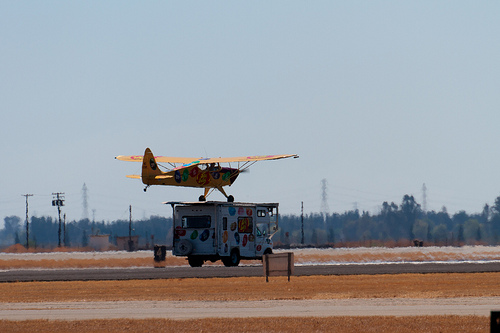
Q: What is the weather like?
A: It is clear.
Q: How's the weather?
A: It is clear.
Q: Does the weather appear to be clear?
A: Yes, it is clear.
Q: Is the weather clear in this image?
A: Yes, it is clear.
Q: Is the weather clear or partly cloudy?
A: It is clear.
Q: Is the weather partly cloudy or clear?
A: It is clear.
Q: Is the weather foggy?
A: No, it is clear.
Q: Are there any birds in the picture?
A: No, there are no birds.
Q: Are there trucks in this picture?
A: Yes, there is a truck.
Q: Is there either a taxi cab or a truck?
A: Yes, there is a truck.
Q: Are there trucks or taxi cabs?
A: Yes, there is a truck.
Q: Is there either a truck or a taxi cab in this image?
A: Yes, there is a truck.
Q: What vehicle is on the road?
A: The vehicle is a truck.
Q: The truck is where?
A: The truck is on the road.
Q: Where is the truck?
A: The truck is on the road.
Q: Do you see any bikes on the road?
A: No, there is a truck on the road.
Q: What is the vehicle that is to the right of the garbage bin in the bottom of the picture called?
A: The vehicle is a truck.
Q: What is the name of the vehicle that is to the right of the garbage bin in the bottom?
A: The vehicle is a truck.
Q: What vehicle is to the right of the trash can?
A: The vehicle is a truck.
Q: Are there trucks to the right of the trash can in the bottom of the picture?
A: Yes, there is a truck to the right of the trashcan.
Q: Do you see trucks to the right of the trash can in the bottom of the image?
A: Yes, there is a truck to the right of the trashcan.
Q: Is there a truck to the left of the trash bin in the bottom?
A: No, the truck is to the right of the garbage can.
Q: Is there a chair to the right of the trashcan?
A: No, there is a truck to the right of the trashcan.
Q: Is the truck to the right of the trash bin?
A: Yes, the truck is to the right of the trash bin.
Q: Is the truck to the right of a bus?
A: No, the truck is to the right of the trash bin.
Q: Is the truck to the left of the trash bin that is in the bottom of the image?
A: No, the truck is to the right of the trash bin.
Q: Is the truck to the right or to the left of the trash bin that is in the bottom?
A: The truck is to the right of the garbage can.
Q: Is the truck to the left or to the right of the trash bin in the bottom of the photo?
A: The truck is to the right of the garbage can.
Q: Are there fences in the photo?
A: No, there are no fences.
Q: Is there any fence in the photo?
A: No, there are no fences.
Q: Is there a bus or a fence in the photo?
A: No, there are no fences or buses.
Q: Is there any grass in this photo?
A: Yes, there is grass.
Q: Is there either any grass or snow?
A: Yes, there is grass.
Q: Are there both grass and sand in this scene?
A: No, there is grass but no sand.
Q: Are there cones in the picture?
A: No, there are no cones.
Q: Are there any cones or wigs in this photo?
A: No, there are no cones or wigs.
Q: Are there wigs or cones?
A: No, there are no cones or wigs.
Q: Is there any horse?
A: No, there are no horses.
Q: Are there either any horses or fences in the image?
A: No, there are no horses or fences.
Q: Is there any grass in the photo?
A: Yes, there is grass.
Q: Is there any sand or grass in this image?
A: Yes, there is grass.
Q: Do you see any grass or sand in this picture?
A: Yes, there is grass.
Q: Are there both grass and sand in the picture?
A: No, there is grass but no sand.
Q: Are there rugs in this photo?
A: No, there are no rugs.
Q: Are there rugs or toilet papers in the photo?
A: No, there are no rugs or toilet papers.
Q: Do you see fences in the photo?
A: No, there are no fences.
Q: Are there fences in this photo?
A: No, there are no fences.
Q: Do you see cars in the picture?
A: No, there are no cars.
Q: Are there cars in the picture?
A: No, there are no cars.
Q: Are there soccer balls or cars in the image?
A: No, there are no cars or soccer balls.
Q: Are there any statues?
A: No, there are no statues.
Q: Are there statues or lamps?
A: No, there are no statues or lamps.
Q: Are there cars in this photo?
A: No, there are no cars.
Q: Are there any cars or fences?
A: No, there are no cars or fences.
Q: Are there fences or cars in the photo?
A: No, there are no cars or fences.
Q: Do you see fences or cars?
A: No, there are no cars or fences.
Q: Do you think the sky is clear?
A: Yes, the sky is clear.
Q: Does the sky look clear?
A: Yes, the sky is clear.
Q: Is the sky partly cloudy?
A: No, the sky is clear.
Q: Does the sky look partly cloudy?
A: No, the sky is clear.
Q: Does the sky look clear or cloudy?
A: The sky is clear.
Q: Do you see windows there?
A: Yes, there is a window.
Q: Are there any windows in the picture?
A: Yes, there is a window.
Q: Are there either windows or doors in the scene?
A: Yes, there is a window.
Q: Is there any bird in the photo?
A: No, there are no birds.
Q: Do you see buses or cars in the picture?
A: No, there are no cars or buses.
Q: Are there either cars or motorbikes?
A: No, there are no cars or motorbikes.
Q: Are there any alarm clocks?
A: No, there are no alarm clocks.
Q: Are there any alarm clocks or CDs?
A: No, there are no alarm clocks or cds.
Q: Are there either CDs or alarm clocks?
A: No, there are no alarm clocks or cds.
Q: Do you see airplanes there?
A: Yes, there is an airplane.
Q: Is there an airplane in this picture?
A: Yes, there is an airplane.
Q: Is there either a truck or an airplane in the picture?
A: Yes, there is an airplane.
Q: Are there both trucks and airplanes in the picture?
A: Yes, there are both an airplane and a truck.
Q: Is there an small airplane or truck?
A: Yes, there is a small airplane.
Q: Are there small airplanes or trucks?
A: Yes, there is a small airplane.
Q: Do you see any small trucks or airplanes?
A: Yes, there is a small airplane.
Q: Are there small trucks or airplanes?
A: Yes, there is a small airplane.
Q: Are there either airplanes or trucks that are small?
A: Yes, the airplane is small.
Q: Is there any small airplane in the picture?
A: Yes, there is a small airplane.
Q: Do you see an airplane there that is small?
A: Yes, there is an airplane that is small.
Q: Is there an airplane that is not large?
A: Yes, there is a small airplane.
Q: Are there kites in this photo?
A: No, there are no kites.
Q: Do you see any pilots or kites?
A: No, there are no kites or pilots.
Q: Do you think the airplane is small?
A: Yes, the airplane is small.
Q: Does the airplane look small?
A: Yes, the airplane is small.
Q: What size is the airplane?
A: The airplane is small.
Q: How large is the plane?
A: The plane is small.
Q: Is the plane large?
A: No, the plane is small.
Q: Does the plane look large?
A: No, the plane is small.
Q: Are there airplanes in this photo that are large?
A: No, there is an airplane but it is small.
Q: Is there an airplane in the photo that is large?
A: No, there is an airplane but it is small.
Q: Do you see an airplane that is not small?
A: No, there is an airplane but it is small.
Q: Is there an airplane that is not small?
A: No, there is an airplane but it is small.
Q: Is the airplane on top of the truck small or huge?
A: The plane is small.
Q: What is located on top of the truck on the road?
A: The airplane is on top of the truck.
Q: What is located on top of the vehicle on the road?
A: The airplane is on top of the truck.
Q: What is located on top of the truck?
A: The airplane is on top of the truck.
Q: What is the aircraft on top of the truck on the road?
A: The aircraft is an airplane.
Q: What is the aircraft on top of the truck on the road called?
A: The aircraft is an airplane.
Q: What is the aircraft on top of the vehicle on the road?
A: The aircraft is an airplane.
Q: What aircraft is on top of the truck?
A: The aircraft is an airplane.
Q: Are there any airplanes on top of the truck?
A: Yes, there is an airplane on top of the truck.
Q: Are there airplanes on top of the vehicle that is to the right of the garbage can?
A: Yes, there is an airplane on top of the truck.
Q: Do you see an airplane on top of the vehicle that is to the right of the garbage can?
A: Yes, there is an airplane on top of the truck.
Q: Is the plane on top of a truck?
A: Yes, the plane is on top of a truck.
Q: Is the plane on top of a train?
A: No, the plane is on top of a truck.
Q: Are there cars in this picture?
A: No, there are no cars.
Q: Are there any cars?
A: No, there are no cars.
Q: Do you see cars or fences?
A: No, there are no cars or fences.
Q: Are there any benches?
A: No, there are no benches.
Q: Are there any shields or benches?
A: No, there are no benches or shields.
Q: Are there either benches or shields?
A: No, there are no benches or shields.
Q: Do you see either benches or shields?
A: No, there are no benches or shields.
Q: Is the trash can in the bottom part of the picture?
A: Yes, the trash can is in the bottom of the image.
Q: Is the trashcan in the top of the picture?
A: No, the trashcan is in the bottom of the image.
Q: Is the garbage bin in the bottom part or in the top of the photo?
A: The garbage bin is in the bottom of the image.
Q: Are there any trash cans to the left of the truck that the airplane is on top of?
A: Yes, there is a trash can to the left of the truck.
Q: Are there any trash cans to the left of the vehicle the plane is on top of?
A: Yes, there is a trash can to the left of the truck.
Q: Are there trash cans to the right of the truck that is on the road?
A: No, the trash can is to the left of the truck.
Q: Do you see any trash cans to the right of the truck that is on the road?
A: No, the trash can is to the left of the truck.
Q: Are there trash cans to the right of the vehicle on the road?
A: No, the trash can is to the left of the truck.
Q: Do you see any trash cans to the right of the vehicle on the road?
A: No, the trash can is to the left of the truck.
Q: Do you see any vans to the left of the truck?
A: No, there is a trash can to the left of the truck.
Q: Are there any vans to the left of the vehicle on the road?
A: No, there is a trash can to the left of the truck.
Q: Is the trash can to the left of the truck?
A: Yes, the trash can is to the left of the truck.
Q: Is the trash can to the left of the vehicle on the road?
A: Yes, the trash can is to the left of the truck.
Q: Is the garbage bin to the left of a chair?
A: No, the garbage bin is to the left of the truck.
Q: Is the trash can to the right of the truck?
A: No, the trash can is to the left of the truck.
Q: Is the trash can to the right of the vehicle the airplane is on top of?
A: No, the trash can is to the left of the truck.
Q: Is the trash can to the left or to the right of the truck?
A: The trash can is to the left of the truck.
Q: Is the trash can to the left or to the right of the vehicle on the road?
A: The trash can is to the left of the truck.